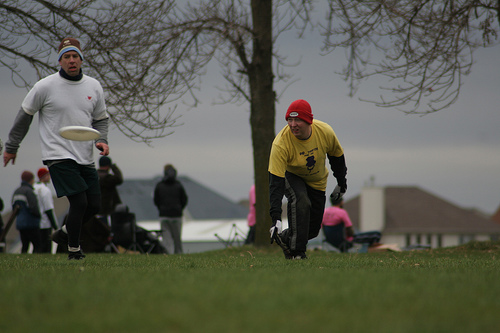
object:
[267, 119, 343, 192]
shirt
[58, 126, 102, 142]
frisbee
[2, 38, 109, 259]
man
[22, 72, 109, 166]
shirt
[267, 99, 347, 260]
man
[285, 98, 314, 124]
cap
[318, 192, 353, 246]
person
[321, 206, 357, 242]
pink shirt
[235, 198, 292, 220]
mountain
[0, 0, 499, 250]
tree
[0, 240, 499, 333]
field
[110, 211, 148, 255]
chair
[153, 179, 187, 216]
jacket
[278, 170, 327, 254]
pants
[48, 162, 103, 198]
shorts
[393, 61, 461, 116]
branch